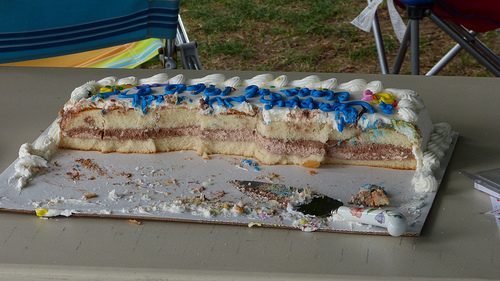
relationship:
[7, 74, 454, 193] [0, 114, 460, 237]
cake on top of sheet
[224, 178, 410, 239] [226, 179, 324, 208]
cake cutter has frosting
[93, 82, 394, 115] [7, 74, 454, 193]
words on top of cake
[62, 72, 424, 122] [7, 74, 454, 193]
frosting on top of cake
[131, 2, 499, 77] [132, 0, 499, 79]
grass growing on ground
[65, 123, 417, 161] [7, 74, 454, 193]
filling inside of cake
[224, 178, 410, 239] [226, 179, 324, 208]
cake cutter covered in frosting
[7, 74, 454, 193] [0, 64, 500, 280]
cake sitting on table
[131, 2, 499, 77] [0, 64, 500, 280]
grass behind table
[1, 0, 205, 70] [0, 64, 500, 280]
picnic chair in front of table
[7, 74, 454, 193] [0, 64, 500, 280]
cake on top of table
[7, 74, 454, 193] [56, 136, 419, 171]
cake has layer